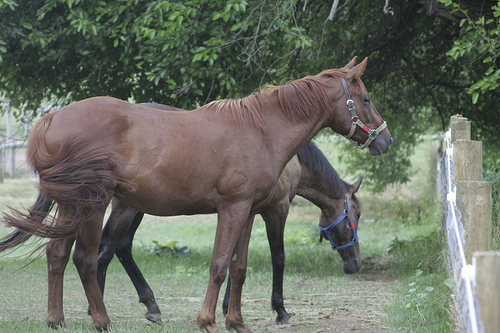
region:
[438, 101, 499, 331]
fence in front of the horses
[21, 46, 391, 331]
horse standing by a fence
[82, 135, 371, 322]
horse bending down towards the grass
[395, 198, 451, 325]
grass growing next to the fence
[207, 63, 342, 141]
hair on the horse's neck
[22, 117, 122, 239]
tail of the horse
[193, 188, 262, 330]
front legs of the horse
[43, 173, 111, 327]
back legs of a horse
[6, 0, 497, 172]
large tree with dense dark green leaves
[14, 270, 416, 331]
area of dirt on the ground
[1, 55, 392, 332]
the two horses standing on the grass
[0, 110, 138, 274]
the tail on the horse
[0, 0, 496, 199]
the trees near the horses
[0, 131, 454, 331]
the green grass around the horses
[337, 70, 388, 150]
the harness on the horse's face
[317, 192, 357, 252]
the harness on the horses face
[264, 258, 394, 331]
the dirt on the ground near the horses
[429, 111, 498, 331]
the fences in front of the horses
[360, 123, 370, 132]
the red part on the harness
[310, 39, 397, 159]
head of a horse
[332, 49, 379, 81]
ear of a horse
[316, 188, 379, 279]
head of a horse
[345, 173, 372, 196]
ear of a horse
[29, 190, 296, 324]
legs of a horse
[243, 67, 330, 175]
neck of a horse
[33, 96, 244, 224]
body of a horse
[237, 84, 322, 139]
hair of a horse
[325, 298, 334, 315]
part of a ground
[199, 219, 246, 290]
aprt of a knee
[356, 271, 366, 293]
part of a ground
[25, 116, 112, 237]
Tail of brown horse swishing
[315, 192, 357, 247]
Blue bridle on dark brown horse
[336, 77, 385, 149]
Tan bridle on light brown horse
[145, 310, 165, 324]
Hoof of dark brown horse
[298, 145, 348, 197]
Mane of dark brown horse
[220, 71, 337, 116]
Mane of light brown horse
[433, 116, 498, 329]
Stone wall keeping horses in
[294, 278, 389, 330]
Patch of dirt amid grass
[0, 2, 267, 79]
Leafy green tree branches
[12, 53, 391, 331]
Two brown horses